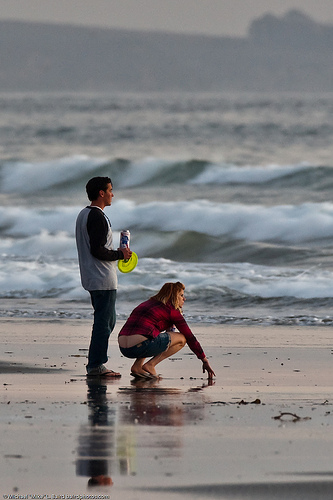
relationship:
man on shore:
[70, 174, 132, 378] [1, 297, 331, 498]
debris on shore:
[234, 398, 330, 419] [192, 159, 329, 479]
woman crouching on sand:
[117, 281, 218, 380] [1, 316, 332, 498]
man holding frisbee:
[70, 174, 132, 378] [117, 248, 139, 275]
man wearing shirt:
[70, 174, 132, 378] [74, 205, 122, 291]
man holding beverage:
[70, 174, 132, 378] [119, 228, 131, 249]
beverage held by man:
[120, 226, 129, 249] [70, 174, 132, 378]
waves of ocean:
[128, 155, 328, 195] [0, 89, 329, 325]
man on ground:
[70, 174, 132, 378] [249, 98, 268, 169]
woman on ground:
[117, 281, 218, 380] [249, 98, 268, 169]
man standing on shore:
[70, 174, 132, 378] [1, 297, 331, 498]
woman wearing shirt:
[117, 281, 218, 380] [117, 292, 205, 358]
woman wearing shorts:
[117, 281, 218, 380] [118, 330, 170, 359]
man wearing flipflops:
[70, 174, 132, 378] [129, 372, 163, 381]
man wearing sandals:
[70, 174, 132, 378] [86, 366, 121, 377]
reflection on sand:
[77, 372, 205, 489] [1, 294, 329, 498]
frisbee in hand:
[117, 248, 137, 273] [116, 243, 133, 261]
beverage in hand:
[119, 228, 131, 249] [118, 247, 131, 261]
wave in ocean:
[0, 120, 333, 143] [0, 89, 329, 325]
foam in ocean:
[197, 258, 326, 301] [0, 89, 329, 325]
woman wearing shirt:
[117, 281, 218, 380] [74, 205, 122, 291]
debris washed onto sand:
[273, 406, 301, 426] [187, 404, 328, 459]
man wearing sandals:
[70, 174, 132, 378] [82, 366, 121, 379]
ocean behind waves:
[0, 89, 329, 325] [2, 156, 332, 189]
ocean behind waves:
[0, 89, 329, 325] [0, 200, 332, 236]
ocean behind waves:
[0, 89, 329, 325] [0, 229, 190, 257]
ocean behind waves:
[0, 89, 329, 325] [1, 254, 332, 297]